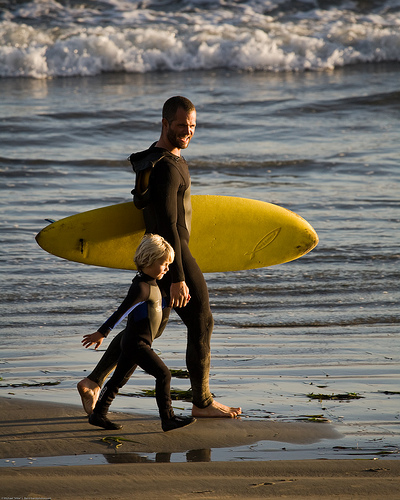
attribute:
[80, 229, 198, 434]
boy — walking, young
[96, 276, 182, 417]
wet suit — light brown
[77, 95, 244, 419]
man — walking, light skinned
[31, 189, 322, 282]
board — surfboard, painted yellow, yellow color, yellow colored, yellow, yellow in color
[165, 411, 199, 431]
shoe — black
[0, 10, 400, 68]
wave — white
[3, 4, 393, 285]
water — body, calm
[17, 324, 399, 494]
sand — brown colored, brown color, brown, a shade of brown, a brown color, brown in color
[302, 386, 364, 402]
seaweed — piled